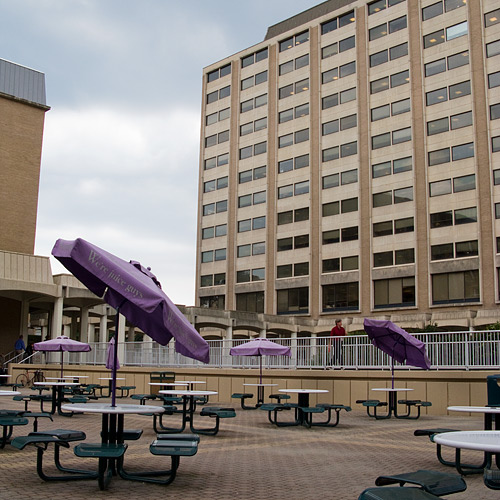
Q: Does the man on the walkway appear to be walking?
A: Yes, the man is walking.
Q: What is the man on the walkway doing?
A: The man is walking.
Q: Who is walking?
A: The man is walking.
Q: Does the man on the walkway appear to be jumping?
A: No, the man is walking.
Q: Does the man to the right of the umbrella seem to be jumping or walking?
A: The man is walking.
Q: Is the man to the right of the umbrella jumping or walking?
A: The man is walking.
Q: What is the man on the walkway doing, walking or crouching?
A: The man is walking.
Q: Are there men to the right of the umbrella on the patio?
A: Yes, there is a man to the right of the umbrella.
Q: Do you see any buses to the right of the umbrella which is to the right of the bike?
A: No, there is a man to the right of the umbrella.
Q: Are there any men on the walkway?
A: Yes, there is a man on the walkway.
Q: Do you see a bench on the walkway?
A: No, there is a man on the walkway.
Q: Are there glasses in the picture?
A: No, there are no glasses.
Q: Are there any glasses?
A: No, there are no glasses.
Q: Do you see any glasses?
A: No, there are no glasses.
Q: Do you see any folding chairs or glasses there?
A: No, there are no glasses or folding chairs.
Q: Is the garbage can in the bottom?
A: Yes, the garbage can is in the bottom of the image.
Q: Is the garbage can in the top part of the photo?
A: No, the garbage can is in the bottom of the image.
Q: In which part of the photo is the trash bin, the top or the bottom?
A: The trash bin is in the bottom of the image.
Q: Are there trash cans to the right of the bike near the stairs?
A: Yes, there is a trash can to the right of the bike.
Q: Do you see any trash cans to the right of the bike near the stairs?
A: Yes, there is a trash can to the right of the bike.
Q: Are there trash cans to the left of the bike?
A: No, the trash can is to the right of the bike.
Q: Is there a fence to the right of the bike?
A: No, there is a trash can to the right of the bike.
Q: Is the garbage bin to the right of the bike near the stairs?
A: Yes, the garbage bin is to the right of the bike.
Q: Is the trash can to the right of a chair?
A: No, the trash can is to the right of the bike.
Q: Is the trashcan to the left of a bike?
A: No, the trashcan is to the right of a bike.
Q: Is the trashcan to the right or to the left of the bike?
A: The trashcan is to the right of the bike.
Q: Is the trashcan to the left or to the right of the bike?
A: The trashcan is to the right of the bike.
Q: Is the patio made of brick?
A: Yes, the patio is made of brick.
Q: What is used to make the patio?
A: The patio is made of brick.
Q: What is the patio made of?
A: The patio is made of brick.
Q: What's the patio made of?
A: The patio is made of brick.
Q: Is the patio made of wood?
A: No, the patio is made of brick.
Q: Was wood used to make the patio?
A: No, the patio is made of brick.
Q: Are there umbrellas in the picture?
A: Yes, there are umbrellas.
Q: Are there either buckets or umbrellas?
A: Yes, there are umbrellas.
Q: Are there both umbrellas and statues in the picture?
A: No, there are umbrellas but no statues.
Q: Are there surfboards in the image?
A: No, there are no surfboards.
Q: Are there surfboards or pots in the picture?
A: No, there are no surfboards or pots.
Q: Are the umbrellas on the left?
A: Yes, the umbrellas are on the left of the image.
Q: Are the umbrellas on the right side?
A: No, the umbrellas are on the left of the image.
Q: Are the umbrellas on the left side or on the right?
A: The umbrellas are on the left of the image.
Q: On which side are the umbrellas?
A: The umbrellas are on the left of the image.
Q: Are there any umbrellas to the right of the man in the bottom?
A: Yes, there are umbrellas to the right of the man.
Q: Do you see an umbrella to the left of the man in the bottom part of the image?
A: No, the umbrellas are to the right of the man.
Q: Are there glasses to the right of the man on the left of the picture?
A: No, there are umbrellas to the right of the man.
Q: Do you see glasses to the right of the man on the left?
A: No, there are umbrellas to the right of the man.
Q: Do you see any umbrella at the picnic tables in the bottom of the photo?
A: Yes, there are umbrellas at the picnic tables.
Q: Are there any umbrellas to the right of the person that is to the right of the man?
A: Yes, there are umbrellas to the right of the person.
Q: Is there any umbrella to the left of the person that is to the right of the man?
A: No, the umbrellas are to the right of the person.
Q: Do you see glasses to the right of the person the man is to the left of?
A: No, there are umbrellas to the right of the person.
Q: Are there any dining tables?
A: Yes, there is a dining table.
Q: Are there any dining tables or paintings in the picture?
A: Yes, there is a dining table.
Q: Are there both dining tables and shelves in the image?
A: No, there is a dining table but no shelves.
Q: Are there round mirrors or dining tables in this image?
A: Yes, there is a round dining table.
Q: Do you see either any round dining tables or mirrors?
A: Yes, there is a round dining table.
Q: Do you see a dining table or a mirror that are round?
A: Yes, the dining table is round.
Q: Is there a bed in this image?
A: No, there are no beds.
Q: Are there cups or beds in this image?
A: No, there are no beds or cups.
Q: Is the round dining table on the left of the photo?
A: Yes, the dining table is on the left of the image.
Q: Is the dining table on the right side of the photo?
A: No, the dining table is on the left of the image.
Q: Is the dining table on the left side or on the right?
A: The dining table is on the left of the image.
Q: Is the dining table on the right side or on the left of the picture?
A: The dining table is on the left of the image.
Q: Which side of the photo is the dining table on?
A: The dining table is on the left of the image.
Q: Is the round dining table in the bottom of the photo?
A: Yes, the dining table is in the bottom of the image.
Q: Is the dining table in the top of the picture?
A: No, the dining table is in the bottom of the image.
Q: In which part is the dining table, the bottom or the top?
A: The dining table is in the bottom of the image.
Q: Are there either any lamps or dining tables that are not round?
A: No, there is a dining table but it is round.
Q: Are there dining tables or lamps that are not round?
A: No, there is a dining table but it is round.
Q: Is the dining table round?
A: Yes, the dining table is round.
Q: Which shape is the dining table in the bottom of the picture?
A: The dining table is round.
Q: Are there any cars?
A: No, there are no cars.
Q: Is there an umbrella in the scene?
A: Yes, there is an umbrella.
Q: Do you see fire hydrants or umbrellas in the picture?
A: Yes, there is an umbrella.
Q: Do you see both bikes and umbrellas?
A: Yes, there are both an umbrella and a bike.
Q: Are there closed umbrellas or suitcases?
A: Yes, there is a closed umbrella.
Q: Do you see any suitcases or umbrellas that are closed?
A: Yes, the umbrella is closed.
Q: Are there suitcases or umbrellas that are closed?
A: Yes, the umbrella is closed.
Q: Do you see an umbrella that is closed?
A: Yes, there is a closed umbrella.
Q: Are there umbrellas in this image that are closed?
A: Yes, there is an umbrella that is closed.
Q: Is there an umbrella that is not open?
A: Yes, there is an closed umbrella.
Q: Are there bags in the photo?
A: No, there are no bags.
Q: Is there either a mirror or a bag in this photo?
A: No, there are no bags or mirrors.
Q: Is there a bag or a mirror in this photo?
A: No, there are no bags or mirrors.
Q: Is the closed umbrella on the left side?
A: Yes, the umbrella is on the left of the image.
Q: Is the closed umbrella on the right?
A: No, the umbrella is on the left of the image.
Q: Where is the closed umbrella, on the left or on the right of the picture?
A: The umbrella is on the left of the image.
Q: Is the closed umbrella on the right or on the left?
A: The umbrella is on the left of the image.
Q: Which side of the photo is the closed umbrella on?
A: The umbrella is on the left of the image.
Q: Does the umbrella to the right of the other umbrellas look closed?
A: Yes, the umbrella is closed.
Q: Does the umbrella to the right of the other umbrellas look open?
A: No, the umbrella is closed.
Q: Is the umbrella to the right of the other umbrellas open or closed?
A: The umbrella is closed.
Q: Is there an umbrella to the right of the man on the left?
A: Yes, there is an umbrella to the right of the man.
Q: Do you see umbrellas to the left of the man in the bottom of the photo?
A: No, the umbrella is to the right of the man.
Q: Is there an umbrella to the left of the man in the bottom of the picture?
A: No, the umbrella is to the right of the man.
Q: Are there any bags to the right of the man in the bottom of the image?
A: No, there is an umbrella to the right of the man.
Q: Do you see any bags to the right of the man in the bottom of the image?
A: No, there is an umbrella to the right of the man.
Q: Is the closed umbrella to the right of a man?
A: Yes, the umbrella is to the right of a man.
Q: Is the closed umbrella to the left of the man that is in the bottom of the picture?
A: No, the umbrella is to the right of the man.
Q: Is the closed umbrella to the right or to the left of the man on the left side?
A: The umbrella is to the right of the man.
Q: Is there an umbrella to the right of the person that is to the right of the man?
A: Yes, there is an umbrella to the right of the person.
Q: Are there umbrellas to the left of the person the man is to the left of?
A: No, the umbrella is to the right of the person.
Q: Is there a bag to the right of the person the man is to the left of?
A: No, there is an umbrella to the right of the person.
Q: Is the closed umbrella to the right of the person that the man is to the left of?
A: Yes, the umbrella is to the right of the person.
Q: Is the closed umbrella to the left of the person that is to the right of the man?
A: No, the umbrella is to the right of the person.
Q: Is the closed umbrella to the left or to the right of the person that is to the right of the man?
A: The umbrella is to the right of the person.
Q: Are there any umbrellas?
A: Yes, there is an umbrella.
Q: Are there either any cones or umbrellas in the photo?
A: Yes, there is an umbrella.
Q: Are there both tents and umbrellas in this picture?
A: No, there is an umbrella but no tents.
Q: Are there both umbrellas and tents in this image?
A: No, there is an umbrella but no tents.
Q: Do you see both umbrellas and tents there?
A: No, there is an umbrella but no tents.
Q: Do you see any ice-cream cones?
A: No, there are no ice-cream cones.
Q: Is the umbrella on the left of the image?
A: Yes, the umbrella is on the left of the image.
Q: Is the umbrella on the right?
A: No, the umbrella is on the left of the image.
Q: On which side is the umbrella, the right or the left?
A: The umbrella is on the left of the image.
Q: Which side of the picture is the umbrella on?
A: The umbrella is on the left of the image.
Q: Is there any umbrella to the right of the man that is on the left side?
A: Yes, there is an umbrella to the right of the man.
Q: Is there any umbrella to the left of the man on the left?
A: No, the umbrella is to the right of the man.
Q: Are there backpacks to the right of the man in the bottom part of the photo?
A: No, there is an umbrella to the right of the man.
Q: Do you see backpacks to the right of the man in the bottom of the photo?
A: No, there is an umbrella to the right of the man.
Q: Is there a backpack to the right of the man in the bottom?
A: No, there is an umbrella to the right of the man.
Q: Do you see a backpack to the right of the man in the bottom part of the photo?
A: No, there is an umbrella to the right of the man.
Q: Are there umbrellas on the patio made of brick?
A: Yes, there is an umbrella on the patio.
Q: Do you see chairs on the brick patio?
A: No, there is an umbrella on the patio.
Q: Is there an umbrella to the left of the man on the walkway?
A: Yes, there is an umbrella to the left of the man.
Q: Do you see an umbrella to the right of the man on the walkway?
A: No, the umbrella is to the left of the man.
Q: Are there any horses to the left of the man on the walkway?
A: No, there is an umbrella to the left of the man.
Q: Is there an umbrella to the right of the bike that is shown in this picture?
A: Yes, there is an umbrella to the right of the bike.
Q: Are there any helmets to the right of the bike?
A: No, there is an umbrella to the right of the bike.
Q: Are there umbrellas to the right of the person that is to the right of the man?
A: Yes, there is an umbrella to the right of the person.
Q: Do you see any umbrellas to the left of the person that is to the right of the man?
A: No, the umbrella is to the right of the person.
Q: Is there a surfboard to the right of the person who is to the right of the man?
A: No, there is an umbrella to the right of the person.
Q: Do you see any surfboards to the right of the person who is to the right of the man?
A: No, there is an umbrella to the right of the person.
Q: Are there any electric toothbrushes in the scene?
A: No, there are no electric toothbrushes.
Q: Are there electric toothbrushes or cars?
A: No, there are no electric toothbrushes or cars.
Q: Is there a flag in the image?
A: No, there are no flags.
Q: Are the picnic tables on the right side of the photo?
A: Yes, the picnic tables are on the right of the image.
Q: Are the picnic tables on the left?
A: No, the picnic tables are on the right of the image.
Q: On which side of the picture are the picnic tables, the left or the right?
A: The picnic tables are on the right of the image.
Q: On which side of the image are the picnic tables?
A: The picnic tables are on the right of the image.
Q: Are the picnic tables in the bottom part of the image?
A: Yes, the picnic tables are in the bottom of the image.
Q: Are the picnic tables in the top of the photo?
A: No, the picnic tables are in the bottom of the image.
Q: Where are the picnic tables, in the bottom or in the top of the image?
A: The picnic tables are in the bottom of the image.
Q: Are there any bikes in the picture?
A: Yes, there is a bike.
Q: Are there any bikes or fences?
A: Yes, there is a bike.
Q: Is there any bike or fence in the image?
A: Yes, there is a bike.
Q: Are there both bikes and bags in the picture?
A: No, there is a bike but no bags.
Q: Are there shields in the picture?
A: No, there are no shields.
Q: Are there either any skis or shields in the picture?
A: No, there are no shields or skis.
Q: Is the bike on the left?
A: Yes, the bike is on the left of the image.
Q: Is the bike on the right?
A: No, the bike is on the left of the image.